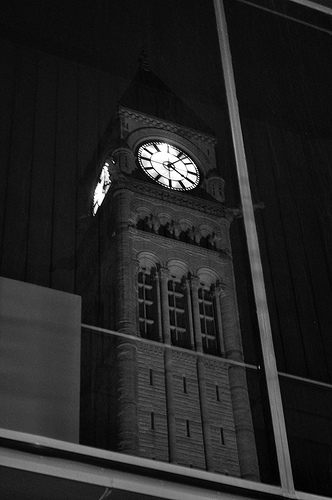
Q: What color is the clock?
A: Black and White.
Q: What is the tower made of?
A: Stone.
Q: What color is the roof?
A: Black.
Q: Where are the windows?
A: On the tower.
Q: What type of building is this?
A: A church.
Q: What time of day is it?
A: Evening.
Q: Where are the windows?
A: In front.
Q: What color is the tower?
A: Grey.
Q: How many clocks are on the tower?
A: 2.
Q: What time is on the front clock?
A: 4:07 AM.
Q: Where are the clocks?
A: Tower.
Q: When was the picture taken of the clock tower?
A: Early morning.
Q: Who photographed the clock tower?
A: Tourist.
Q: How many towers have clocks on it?
A: 1.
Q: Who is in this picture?
A: No one.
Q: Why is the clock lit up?
A: It's dark.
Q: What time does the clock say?
A: 4:06.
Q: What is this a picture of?
A: Clock tower.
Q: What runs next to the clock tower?
A: A pole.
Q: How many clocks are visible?
A: Two.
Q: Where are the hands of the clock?
A: On the clock face.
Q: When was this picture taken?
A: Night time.